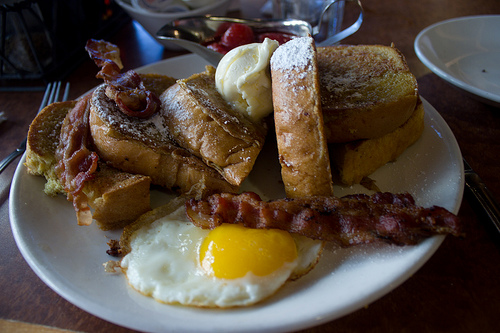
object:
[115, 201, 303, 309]
eggs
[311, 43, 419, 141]
bread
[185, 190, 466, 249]
bacon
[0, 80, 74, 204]
fork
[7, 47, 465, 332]
plate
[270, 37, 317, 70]
sugar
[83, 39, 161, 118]
bacon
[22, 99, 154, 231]
french toast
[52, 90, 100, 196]
bacon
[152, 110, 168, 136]
sugar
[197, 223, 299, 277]
yolk